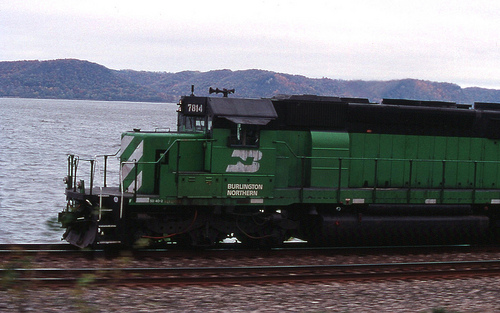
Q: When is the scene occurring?
A: Early morning.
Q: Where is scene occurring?
A: Train tracks by lake.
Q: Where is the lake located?
A: Behind train.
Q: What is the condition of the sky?
A: Cloudy.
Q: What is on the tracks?
A: A green train.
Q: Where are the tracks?
A: Under the train.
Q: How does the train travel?
A: Moves along tracks.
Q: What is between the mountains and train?
A: Water.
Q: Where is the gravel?
A: By the train tracks.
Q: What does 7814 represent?
A: The train number.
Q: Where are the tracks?
A: Alongside the water.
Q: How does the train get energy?
A: Engine.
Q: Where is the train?
A: On the track.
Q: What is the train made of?
A: Metal.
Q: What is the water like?
A: Flat.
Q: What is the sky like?
A: Cloudy.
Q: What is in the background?
A: Mountains.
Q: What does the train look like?
A: Black and green.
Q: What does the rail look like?
A: Rusted.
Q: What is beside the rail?
A: Gravel.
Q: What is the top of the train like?
A: Black.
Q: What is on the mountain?
A: Trees.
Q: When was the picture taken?
A: Daytime.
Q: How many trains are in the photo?
A: One.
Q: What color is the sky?
A: White.